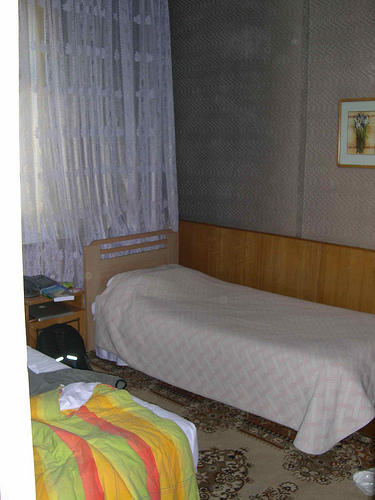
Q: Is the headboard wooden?
A: Yes, the headboard is wooden.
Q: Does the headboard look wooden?
A: Yes, the headboard is wooden.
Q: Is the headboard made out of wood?
A: Yes, the headboard is made of wood.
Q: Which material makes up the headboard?
A: The headboard is made of wood.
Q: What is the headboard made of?
A: The headboard is made of wood.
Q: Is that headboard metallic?
A: No, the headboard is wooden.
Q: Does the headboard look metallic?
A: No, the headboard is wooden.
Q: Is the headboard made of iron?
A: No, the headboard is made of wood.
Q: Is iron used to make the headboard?
A: No, the headboard is made of wood.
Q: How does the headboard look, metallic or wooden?
A: The headboard is wooden.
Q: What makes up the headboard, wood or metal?
A: The headboard is made of wood.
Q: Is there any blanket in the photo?
A: Yes, there is a blanket.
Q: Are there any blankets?
A: Yes, there is a blanket.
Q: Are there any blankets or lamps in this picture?
A: Yes, there is a blanket.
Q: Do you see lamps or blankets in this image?
A: Yes, there is a blanket.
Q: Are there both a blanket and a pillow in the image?
A: Yes, there are both a blanket and a pillow.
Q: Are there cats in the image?
A: No, there are no cats.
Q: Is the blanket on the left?
A: Yes, the blanket is on the left of the image.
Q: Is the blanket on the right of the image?
A: No, the blanket is on the left of the image.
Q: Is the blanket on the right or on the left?
A: The blanket is on the left of the image.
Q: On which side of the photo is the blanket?
A: The blanket is on the left of the image.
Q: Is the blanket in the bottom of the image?
A: Yes, the blanket is in the bottom of the image.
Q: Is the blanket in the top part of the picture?
A: No, the blanket is in the bottom of the image.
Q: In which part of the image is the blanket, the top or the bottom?
A: The blanket is in the bottom of the image.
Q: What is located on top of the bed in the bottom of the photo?
A: The blanket is on top of the bed.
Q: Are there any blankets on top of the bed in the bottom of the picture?
A: Yes, there is a blanket on top of the bed.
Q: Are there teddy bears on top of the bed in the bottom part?
A: No, there is a blanket on top of the bed.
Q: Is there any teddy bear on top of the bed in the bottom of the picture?
A: No, there is a blanket on top of the bed.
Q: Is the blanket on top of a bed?
A: Yes, the blanket is on top of a bed.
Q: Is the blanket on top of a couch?
A: No, the blanket is on top of a bed.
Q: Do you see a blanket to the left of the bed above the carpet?
A: Yes, there is a blanket to the left of the bed.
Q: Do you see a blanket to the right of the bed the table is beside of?
A: No, the blanket is to the left of the bed.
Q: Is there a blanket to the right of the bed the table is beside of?
A: No, the blanket is to the left of the bed.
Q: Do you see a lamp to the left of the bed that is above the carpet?
A: No, there is a blanket to the left of the bed.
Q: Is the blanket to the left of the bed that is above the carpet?
A: Yes, the blanket is to the left of the bed.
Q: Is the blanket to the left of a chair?
A: No, the blanket is to the left of the bed.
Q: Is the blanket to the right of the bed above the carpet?
A: No, the blanket is to the left of the bed.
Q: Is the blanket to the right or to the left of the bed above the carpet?
A: The blanket is to the left of the bed.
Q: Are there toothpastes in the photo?
A: No, there are no toothpastes.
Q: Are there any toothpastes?
A: No, there are no toothpastes.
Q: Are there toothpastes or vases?
A: No, there are no toothpastes or vases.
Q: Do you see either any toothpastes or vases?
A: No, there are no toothpastes or vases.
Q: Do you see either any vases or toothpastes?
A: No, there are no toothpastes or vases.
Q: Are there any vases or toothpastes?
A: No, there are no toothpastes or vases.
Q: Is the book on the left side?
A: Yes, the book is on the left of the image.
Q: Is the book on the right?
A: No, the book is on the left of the image.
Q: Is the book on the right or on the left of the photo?
A: The book is on the left of the image.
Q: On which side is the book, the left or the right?
A: The book is on the left of the image.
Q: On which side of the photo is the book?
A: The book is on the left of the image.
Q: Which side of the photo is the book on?
A: The book is on the left of the image.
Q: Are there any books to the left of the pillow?
A: Yes, there is a book to the left of the pillow.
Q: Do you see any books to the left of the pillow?
A: Yes, there is a book to the left of the pillow.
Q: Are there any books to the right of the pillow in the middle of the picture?
A: No, the book is to the left of the pillow.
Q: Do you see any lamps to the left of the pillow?
A: No, there is a book to the left of the pillow.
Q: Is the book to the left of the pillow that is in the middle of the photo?
A: Yes, the book is to the left of the pillow.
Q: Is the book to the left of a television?
A: No, the book is to the left of the pillow.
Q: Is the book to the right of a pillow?
A: No, the book is to the left of a pillow.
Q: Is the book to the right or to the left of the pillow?
A: The book is to the left of the pillow.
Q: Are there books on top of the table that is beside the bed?
A: Yes, there is a book on top of the table.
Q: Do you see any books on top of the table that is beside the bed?
A: Yes, there is a book on top of the table.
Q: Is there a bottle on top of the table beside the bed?
A: No, there is a book on top of the table.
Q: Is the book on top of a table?
A: Yes, the book is on top of a table.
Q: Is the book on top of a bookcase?
A: No, the book is on top of a table.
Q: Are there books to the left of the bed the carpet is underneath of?
A: Yes, there is a book to the left of the bed.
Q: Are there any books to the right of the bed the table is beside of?
A: No, the book is to the left of the bed.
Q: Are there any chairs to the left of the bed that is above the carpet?
A: No, there is a book to the left of the bed.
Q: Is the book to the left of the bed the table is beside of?
A: Yes, the book is to the left of the bed.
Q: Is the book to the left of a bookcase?
A: No, the book is to the left of the bed.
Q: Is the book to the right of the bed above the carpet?
A: No, the book is to the left of the bed.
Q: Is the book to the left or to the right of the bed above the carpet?
A: The book is to the left of the bed.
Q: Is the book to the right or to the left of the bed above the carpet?
A: The book is to the left of the bed.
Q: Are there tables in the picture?
A: Yes, there is a table.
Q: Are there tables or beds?
A: Yes, there is a table.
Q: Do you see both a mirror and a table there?
A: No, there is a table but no mirrors.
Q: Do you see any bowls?
A: No, there are no bowls.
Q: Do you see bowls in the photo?
A: No, there are no bowls.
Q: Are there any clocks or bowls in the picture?
A: No, there are no bowls or clocks.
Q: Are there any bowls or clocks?
A: No, there are no bowls or clocks.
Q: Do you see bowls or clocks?
A: No, there are no bowls or clocks.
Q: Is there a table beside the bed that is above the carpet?
A: Yes, there is a table beside the bed.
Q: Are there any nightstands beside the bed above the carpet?
A: No, there is a table beside the bed.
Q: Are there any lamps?
A: No, there are no lamps.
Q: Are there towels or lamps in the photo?
A: No, there are no lamps or towels.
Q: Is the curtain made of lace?
A: Yes, the curtain is made of lace.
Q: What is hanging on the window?
A: The curtain is hanging on the window.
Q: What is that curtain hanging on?
A: The curtain is hanging on the window.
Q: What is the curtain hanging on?
A: The curtain is hanging on the window.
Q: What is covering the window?
A: The curtain is covering the window.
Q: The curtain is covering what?
A: The curtain is covering the window.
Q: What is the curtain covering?
A: The curtain is covering the window.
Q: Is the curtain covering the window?
A: Yes, the curtain is covering the window.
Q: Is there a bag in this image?
A: Yes, there is a bag.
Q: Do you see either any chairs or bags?
A: Yes, there is a bag.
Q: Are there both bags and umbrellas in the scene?
A: No, there is a bag but no umbrellas.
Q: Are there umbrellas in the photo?
A: No, there are no umbrellas.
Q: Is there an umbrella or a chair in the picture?
A: No, there are no umbrellas or chairs.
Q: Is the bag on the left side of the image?
A: Yes, the bag is on the left of the image.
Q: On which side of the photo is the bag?
A: The bag is on the left of the image.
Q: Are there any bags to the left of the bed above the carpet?
A: Yes, there is a bag to the left of the bed.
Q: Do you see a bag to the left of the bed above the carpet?
A: Yes, there is a bag to the left of the bed.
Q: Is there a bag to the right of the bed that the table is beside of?
A: No, the bag is to the left of the bed.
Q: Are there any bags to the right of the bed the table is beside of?
A: No, the bag is to the left of the bed.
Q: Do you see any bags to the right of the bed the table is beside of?
A: No, the bag is to the left of the bed.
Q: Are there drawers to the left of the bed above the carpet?
A: No, there is a bag to the left of the bed.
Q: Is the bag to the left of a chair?
A: No, the bag is to the left of a bed.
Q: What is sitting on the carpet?
A: The bag is sitting on the carpet.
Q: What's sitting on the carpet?
A: The bag is sitting on the carpet.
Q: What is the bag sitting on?
A: The bag is sitting on the carpet.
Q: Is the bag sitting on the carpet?
A: Yes, the bag is sitting on the carpet.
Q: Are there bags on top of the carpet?
A: Yes, there is a bag on top of the carpet.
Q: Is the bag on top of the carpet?
A: Yes, the bag is on top of the carpet.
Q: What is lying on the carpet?
A: The bag is lying on the carpet.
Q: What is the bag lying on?
A: The bag is lying on the carpet.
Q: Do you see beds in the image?
A: Yes, there is a bed.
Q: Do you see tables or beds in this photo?
A: Yes, there is a bed.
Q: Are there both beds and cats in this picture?
A: No, there is a bed but no cats.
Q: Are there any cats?
A: No, there are no cats.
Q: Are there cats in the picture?
A: No, there are no cats.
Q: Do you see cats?
A: No, there are no cats.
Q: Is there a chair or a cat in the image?
A: No, there are no cats or chairs.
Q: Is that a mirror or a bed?
A: That is a bed.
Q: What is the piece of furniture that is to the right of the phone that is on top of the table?
A: The piece of furniture is a bed.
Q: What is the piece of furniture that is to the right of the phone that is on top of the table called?
A: The piece of furniture is a bed.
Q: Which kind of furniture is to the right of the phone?
A: The piece of furniture is a bed.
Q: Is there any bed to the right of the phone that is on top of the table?
A: Yes, there is a bed to the right of the phone.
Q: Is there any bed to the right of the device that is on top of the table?
A: Yes, there is a bed to the right of the phone.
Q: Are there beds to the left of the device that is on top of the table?
A: No, the bed is to the right of the telephone.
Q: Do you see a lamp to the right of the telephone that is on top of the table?
A: No, there is a bed to the right of the phone.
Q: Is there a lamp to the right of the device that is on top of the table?
A: No, there is a bed to the right of the phone.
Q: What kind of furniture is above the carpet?
A: The piece of furniture is a bed.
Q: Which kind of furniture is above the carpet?
A: The piece of furniture is a bed.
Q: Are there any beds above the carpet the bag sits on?
A: Yes, there is a bed above the carpet.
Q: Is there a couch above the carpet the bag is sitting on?
A: No, there is a bed above the carpet.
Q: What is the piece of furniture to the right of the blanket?
A: The piece of furniture is a bed.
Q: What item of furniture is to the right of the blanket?
A: The piece of furniture is a bed.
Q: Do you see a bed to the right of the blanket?
A: Yes, there is a bed to the right of the blanket.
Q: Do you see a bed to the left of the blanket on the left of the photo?
A: No, the bed is to the right of the blanket.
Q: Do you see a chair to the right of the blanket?
A: No, there is a bed to the right of the blanket.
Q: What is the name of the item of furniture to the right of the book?
A: The piece of furniture is a bed.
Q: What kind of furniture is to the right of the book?
A: The piece of furniture is a bed.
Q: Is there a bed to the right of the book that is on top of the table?
A: Yes, there is a bed to the right of the book.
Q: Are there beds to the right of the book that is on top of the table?
A: Yes, there is a bed to the right of the book.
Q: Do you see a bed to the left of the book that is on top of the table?
A: No, the bed is to the right of the book.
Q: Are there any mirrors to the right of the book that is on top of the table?
A: No, there is a bed to the right of the book.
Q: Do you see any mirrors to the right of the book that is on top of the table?
A: No, there is a bed to the right of the book.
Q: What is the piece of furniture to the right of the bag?
A: The piece of furniture is a bed.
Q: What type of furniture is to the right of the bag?
A: The piece of furniture is a bed.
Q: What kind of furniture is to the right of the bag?
A: The piece of furniture is a bed.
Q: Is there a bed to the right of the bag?
A: Yes, there is a bed to the right of the bag.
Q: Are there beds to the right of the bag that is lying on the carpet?
A: Yes, there is a bed to the right of the bag.